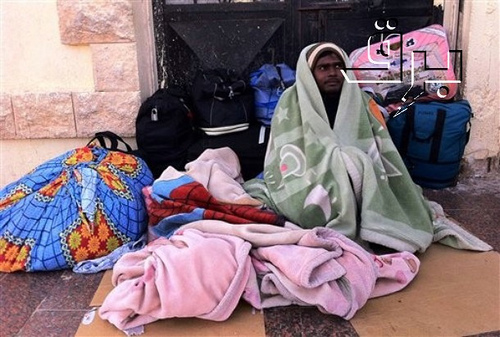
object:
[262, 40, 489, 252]
man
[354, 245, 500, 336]
cardboard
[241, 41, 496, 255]
blanket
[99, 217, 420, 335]
blanket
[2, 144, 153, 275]
blanket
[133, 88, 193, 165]
bag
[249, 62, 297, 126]
bag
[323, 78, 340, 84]
mustache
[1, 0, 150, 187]
wall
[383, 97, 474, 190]
bag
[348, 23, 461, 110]
suitcase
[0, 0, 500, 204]
building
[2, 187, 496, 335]
sidewalk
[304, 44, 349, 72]
cap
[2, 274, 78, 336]
floor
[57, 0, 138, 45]
stones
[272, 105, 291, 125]
star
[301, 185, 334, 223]
moon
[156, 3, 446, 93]
door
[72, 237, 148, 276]
clothes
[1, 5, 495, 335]
picture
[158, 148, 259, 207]
sheets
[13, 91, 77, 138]
bricks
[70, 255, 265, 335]
cardboard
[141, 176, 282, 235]
sheet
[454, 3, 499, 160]
wall